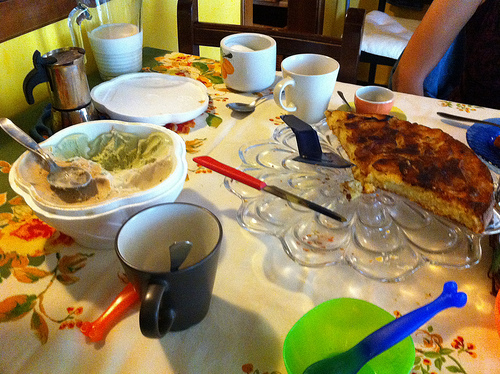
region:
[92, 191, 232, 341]
black coffee cup with white on the inside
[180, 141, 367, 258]
dirty red handle knife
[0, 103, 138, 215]
dirty silver spoon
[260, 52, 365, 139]
white coffee cup with handle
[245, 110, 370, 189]
black cake server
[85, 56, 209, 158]
plastic container lid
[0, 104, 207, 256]
plastic container filled with food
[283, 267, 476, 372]
blue plastic spoon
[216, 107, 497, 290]
beautiful glass plate with food on it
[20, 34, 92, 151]
silver coffer container with black handle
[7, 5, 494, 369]
A table scene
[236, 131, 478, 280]
A glass serving plate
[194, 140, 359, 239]
A knife is on the plate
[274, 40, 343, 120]
A white mug is on the table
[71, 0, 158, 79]
A pitcher of milk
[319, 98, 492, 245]
A tart is on the plate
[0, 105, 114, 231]
A spoon is in this bowl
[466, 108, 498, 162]
A blue plate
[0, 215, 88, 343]
A floral pattern is on the tablecloth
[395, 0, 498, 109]
A person is standing here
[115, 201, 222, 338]
an empty dark gray coffee cup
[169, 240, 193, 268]
the handle of a spoon in the coffee cup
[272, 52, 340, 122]
a white coffee cup on the table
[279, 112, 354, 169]
a blue cake and pie knife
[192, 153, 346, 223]
a knife with red handle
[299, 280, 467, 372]
a blue plastic spoon in a green bowl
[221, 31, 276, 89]
a white sugar cup holder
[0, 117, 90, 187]
a stainless steel spoon in a white container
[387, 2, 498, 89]
the arm of a person at the table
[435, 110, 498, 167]
the handle of a metal silverware on the edge of a blue plate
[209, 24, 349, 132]
the cups are white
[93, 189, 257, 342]
the cup is black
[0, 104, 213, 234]
the spoon is in bowl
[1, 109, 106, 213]
the spoon is silver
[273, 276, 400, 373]
the cup is green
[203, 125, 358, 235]
knife on glass tray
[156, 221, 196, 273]
spoon in the cup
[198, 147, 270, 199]
handle of knife is red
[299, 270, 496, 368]
the spoon is blue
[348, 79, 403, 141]
the cup is orange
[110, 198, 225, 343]
coffe cup on table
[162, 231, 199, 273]
utensil handle on cup rim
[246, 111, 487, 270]
partial cake on stand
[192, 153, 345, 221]
knife with red handle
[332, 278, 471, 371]
blue plastic utensil in bowl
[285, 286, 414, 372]
round green plastic bowl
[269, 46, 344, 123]
white cup with handle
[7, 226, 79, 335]
flower design on tablecloth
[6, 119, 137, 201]
spoon in white bowl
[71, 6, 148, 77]
milk in glass pitcher